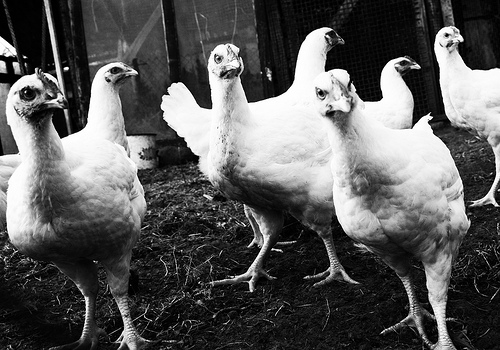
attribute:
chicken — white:
[185, 32, 348, 242]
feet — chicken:
[211, 227, 361, 297]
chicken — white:
[5, 72, 162, 339]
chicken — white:
[321, 67, 476, 343]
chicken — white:
[208, 36, 329, 217]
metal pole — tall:
[70, 11, 86, 89]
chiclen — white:
[290, 23, 347, 104]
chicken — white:
[428, 19, 495, 209]